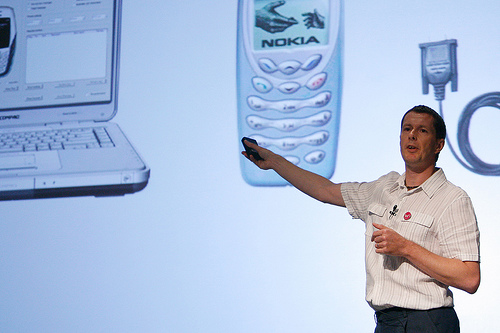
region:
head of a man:
[371, 81, 454, 183]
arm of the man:
[236, 130, 371, 235]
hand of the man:
[349, 222, 406, 272]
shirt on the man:
[352, 169, 484, 286]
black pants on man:
[367, 299, 455, 331]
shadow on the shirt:
[367, 254, 404, 279]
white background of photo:
[122, 201, 269, 297]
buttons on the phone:
[245, 58, 343, 148]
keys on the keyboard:
[10, 116, 108, 165]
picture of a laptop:
[4, 82, 164, 243]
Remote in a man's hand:
[240, 136, 265, 157]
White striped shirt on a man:
[342, 168, 479, 303]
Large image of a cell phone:
[233, 2, 341, 179]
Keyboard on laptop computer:
[0, 124, 118, 158]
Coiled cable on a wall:
[442, 93, 497, 180]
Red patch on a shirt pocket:
[400, 210, 414, 220]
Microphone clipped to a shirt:
[386, 204, 397, 217]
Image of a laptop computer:
[0, 2, 151, 198]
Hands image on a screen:
[255, 3, 324, 38]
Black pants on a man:
[370, 300, 455, 332]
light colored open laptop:
[3, 4, 153, 196]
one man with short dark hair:
[396, 104, 448, 179]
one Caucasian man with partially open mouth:
[395, 104, 447, 170]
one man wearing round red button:
[378, 102, 452, 227]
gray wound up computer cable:
[411, 28, 499, 182]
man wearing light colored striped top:
[343, 97, 480, 309]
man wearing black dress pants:
[337, 104, 474, 332]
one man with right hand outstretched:
[232, 100, 485, 309]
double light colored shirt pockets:
[366, 196, 439, 244]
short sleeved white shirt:
[338, 171, 480, 309]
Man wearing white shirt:
[349, 98, 482, 309]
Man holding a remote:
[240, 115, 484, 321]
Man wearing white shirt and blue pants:
[339, 104, 486, 331]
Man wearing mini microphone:
[331, 100, 481, 306]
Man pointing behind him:
[266, 105, 491, 330]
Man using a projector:
[227, 0, 474, 330]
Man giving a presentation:
[38, 19, 498, 328]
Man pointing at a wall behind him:
[197, 9, 490, 331]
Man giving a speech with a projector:
[218, 80, 491, 331]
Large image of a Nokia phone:
[194, 6, 359, 141]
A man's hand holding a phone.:
[231, 129, 292, 179]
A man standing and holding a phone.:
[230, 98, 479, 331]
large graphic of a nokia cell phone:
[222, 21, 350, 183]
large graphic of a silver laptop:
[0, 3, 202, 225]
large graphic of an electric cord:
[416, 25, 498, 191]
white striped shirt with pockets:
[337, 169, 491, 324]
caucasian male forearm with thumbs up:
[367, 213, 491, 298]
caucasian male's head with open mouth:
[387, 97, 450, 199]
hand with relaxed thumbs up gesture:
[362, 216, 414, 266]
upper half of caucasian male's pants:
[339, 297, 466, 330]